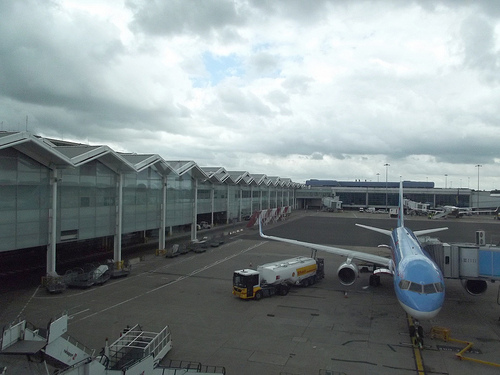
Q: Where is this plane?
A: Airport.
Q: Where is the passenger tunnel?
A: Connected to the plane.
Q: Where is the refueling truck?
A: Left of the plane.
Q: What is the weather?
A: Overcast.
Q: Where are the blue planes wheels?
A: On the ground.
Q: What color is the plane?
A: Blue and white.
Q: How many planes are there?
A: One.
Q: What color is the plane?
A: Blue and white.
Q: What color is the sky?
A: Blue.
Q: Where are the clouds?
A: In the sky.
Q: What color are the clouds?
A: White and gray.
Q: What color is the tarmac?
A: Gray.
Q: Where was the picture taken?
A: At an airport.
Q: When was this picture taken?
A: Daytime.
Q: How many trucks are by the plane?
A: One.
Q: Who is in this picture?
A: No one.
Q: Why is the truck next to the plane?
A: To refuel.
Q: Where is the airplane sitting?
A: On the tarmac.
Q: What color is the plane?
A: Blue and white.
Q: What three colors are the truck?
A: Black, yellow, and white.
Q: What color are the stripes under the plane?
A: Yellow and black.